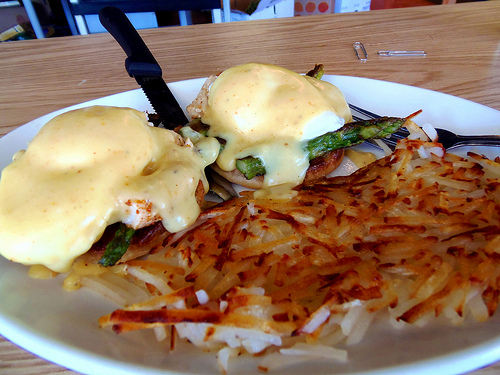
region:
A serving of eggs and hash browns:
[13, 50, 486, 352]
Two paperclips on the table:
[343, 24, 443, 71]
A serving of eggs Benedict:
[10, 68, 359, 251]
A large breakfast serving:
[15, 60, 480, 352]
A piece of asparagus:
[229, 109, 416, 188]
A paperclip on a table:
[345, 22, 375, 77]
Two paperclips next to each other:
[346, 35, 435, 70]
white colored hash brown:
[278, 340, 348, 361]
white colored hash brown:
[348, 311, 373, 343]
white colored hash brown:
[341, 303, 360, 333]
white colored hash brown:
[239, 336, 268, 352]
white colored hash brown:
[215, 343, 233, 373]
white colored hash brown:
[211, 323, 281, 348]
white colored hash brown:
[80, 278, 125, 303]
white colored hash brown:
[94, 275, 139, 302]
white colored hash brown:
[127, 267, 170, 294]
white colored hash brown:
[472, 296, 489, 321]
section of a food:
[200, 252, 295, 362]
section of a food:
[100, 202, 202, 312]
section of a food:
[266, 76, 423, 251]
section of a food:
[121, 132, 277, 280]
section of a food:
[162, 209, 344, 371]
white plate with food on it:
[2, 70, 498, 372]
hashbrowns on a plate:
[79, 117, 498, 372]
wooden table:
[1, 0, 498, 372]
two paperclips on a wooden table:
[351, 40, 424, 62]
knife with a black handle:
[99, 5, 189, 129]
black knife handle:
[99, 5, 162, 71]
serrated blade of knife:
[136, 72, 187, 129]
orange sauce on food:
[0, 107, 209, 271]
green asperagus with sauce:
[237, 115, 402, 182]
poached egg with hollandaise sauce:
[1, 98, 203, 274]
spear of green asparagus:
[224, 111, 411, 183]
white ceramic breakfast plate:
[1, 70, 496, 374]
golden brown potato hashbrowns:
[98, 132, 498, 373]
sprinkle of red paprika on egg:
[103, 179, 215, 229]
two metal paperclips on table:
[347, 33, 432, 70]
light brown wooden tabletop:
[1, 1, 496, 373]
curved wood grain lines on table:
[325, 58, 442, 90]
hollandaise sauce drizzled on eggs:
[199, 53, 347, 188]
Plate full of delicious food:
[1, 61, 499, 373]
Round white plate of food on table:
[0, 60, 499, 374]